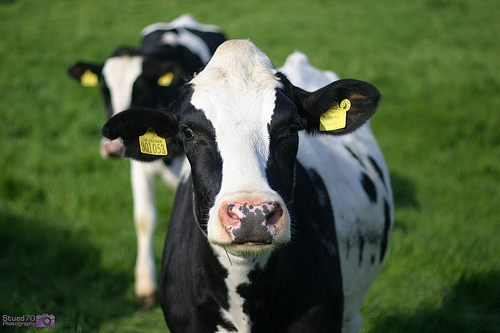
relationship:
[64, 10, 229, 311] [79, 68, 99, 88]
cow wearing tag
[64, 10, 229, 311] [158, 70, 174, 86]
cow wearing tag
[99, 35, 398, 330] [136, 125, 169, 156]
cow wearing tag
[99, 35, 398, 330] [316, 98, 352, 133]
cow wearing tag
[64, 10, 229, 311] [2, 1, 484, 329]
cow standing in grass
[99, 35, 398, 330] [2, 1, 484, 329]
cow standing in grass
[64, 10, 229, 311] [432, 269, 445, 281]
cow walking during bad sentence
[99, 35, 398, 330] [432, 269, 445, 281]
cow walking during bad sentence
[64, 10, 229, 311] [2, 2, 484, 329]
cow walking during day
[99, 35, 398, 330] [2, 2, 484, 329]
cow walking during day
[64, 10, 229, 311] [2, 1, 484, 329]
cow walking in grass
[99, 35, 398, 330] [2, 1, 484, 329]
cow walking in grass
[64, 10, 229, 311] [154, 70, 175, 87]
cow wearing tag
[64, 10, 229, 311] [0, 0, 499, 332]
cow walking in field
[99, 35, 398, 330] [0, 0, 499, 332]
cow walking in field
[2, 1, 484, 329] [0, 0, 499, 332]
grass covering field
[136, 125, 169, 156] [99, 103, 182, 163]
tag pinned in ear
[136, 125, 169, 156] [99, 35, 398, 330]
tag on cow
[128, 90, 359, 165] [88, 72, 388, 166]
tags on ears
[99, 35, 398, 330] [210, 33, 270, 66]
cow has lump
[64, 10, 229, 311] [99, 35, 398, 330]
cow next cow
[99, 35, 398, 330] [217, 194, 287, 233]
cow has snout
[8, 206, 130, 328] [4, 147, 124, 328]
shadow on grass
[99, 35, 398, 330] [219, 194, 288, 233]
cow has nose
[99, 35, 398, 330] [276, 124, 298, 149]
cow has eye